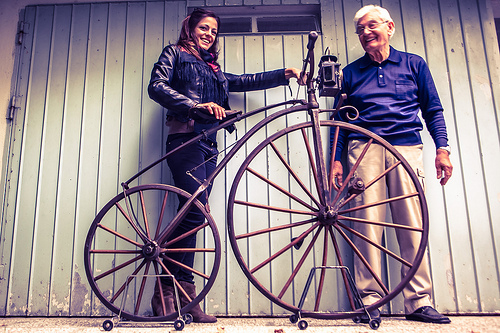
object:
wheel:
[227, 119, 430, 320]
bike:
[83, 30, 428, 333]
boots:
[150, 278, 216, 324]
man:
[329, 5, 453, 324]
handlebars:
[296, 31, 318, 86]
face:
[193, 16, 218, 50]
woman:
[146, 8, 305, 324]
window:
[188, 4, 320, 35]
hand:
[196, 102, 226, 121]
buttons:
[378, 66, 384, 70]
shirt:
[330, 45, 448, 163]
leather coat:
[148, 43, 290, 133]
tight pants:
[159, 131, 219, 287]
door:
[82, 40, 129, 157]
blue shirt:
[328, 44, 449, 165]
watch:
[439, 146, 451, 154]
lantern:
[319, 49, 343, 98]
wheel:
[84, 183, 221, 322]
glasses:
[356, 21, 388, 35]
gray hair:
[352, 4, 396, 40]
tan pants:
[346, 140, 436, 315]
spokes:
[337, 192, 416, 215]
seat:
[190, 108, 242, 124]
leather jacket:
[179, 55, 197, 83]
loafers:
[405, 305, 452, 323]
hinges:
[16, 23, 24, 45]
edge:
[334, 120, 347, 129]